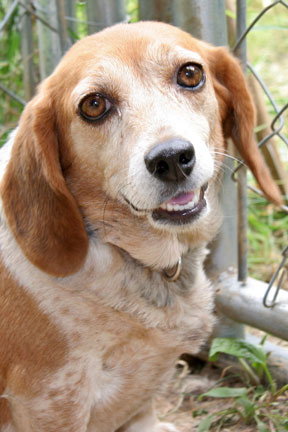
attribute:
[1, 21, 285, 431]
dog — brown, light-brown, staring, looking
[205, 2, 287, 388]
fence — chain-link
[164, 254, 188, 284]
ring — silver, round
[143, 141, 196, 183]
nose — black, shiny, wet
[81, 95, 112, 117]
eye — brown, orange, round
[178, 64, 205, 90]
eye — brown, round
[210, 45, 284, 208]
ear — floppy, long, brown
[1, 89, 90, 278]
ear — long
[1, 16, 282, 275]
head — light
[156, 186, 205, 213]
mouth — pink, open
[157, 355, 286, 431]
ground — green